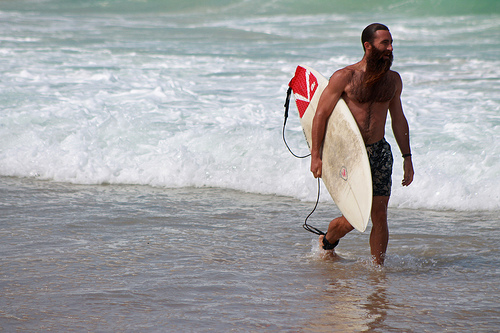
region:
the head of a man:
[356, 24, 417, 99]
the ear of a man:
[358, 36, 377, 64]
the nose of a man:
[373, 33, 405, 64]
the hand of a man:
[285, 163, 345, 225]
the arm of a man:
[281, 75, 375, 211]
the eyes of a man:
[362, 30, 401, 75]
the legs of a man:
[306, 126, 445, 269]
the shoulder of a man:
[320, 45, 354, 103]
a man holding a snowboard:
[241, 26, 430, 237]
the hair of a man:
[352, 18, 386, 50]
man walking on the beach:
[309, 19, 414, 276]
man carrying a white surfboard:
[287, 65, 372, 235]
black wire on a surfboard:
[283, 86, 325, 234]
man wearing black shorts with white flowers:
[361, 141, 393, 196]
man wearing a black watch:
[398, 150, 413, 158]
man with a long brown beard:
[366, 45, 394, 72]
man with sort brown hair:
[360, 22, 394, 72]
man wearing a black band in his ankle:
[319, 233, 338, 250]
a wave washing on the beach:
[0, 52, 499, 208]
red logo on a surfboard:
[288, 65, 319, 117]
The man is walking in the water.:
[234, 15, 429, 293]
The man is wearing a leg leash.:
[268, 15, 458, 297]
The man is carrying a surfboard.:
[252, 20, 444, 282]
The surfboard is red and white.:
[262, 13, 442, 286]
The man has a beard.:
[273, 18, 432, 281]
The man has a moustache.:
[257, 13, 447, 287]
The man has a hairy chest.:
[263, 11, 442, 298]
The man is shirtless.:
[261, 13, 436, 283]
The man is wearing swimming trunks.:
[262, 12, 430, 292]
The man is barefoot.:
[256, 10, 433, 286]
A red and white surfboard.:
[291, 63, 371, 231]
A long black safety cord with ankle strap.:
[282, 86, 339, 249]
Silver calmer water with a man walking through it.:
[0, 173, 497, 328]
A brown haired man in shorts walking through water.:
[309, 20, 413, 265]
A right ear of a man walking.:
[362, 40, 372, 48]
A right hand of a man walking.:
[308, 157, 323, 177]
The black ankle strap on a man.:
[321, 233, 339, 250]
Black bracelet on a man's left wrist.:
[401, 150, 413, 159]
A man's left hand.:
[400, 158, 415, 188]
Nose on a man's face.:
[385, 38, 392, 53]